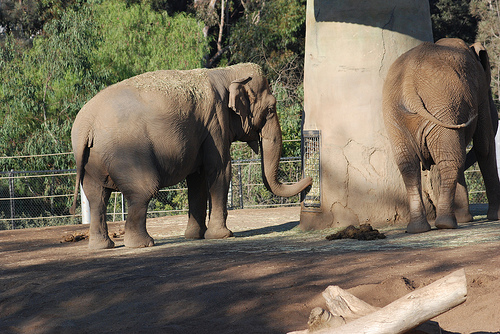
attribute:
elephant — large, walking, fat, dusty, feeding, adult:
[68, 61, 313, 250]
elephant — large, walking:
[383, 36, 499, 235]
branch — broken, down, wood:
[286, 268, 468, 333]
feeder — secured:
[301, 129, 323, 208]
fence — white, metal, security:
[2, 137, 489, 232]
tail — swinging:
[401, 93, 481, 130]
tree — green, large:
[2, 1, 206, 217]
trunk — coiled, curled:
[257, 116, 314, 197]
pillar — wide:
[297, 0, 476, 233]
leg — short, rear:
[107, 126, 159, 249]